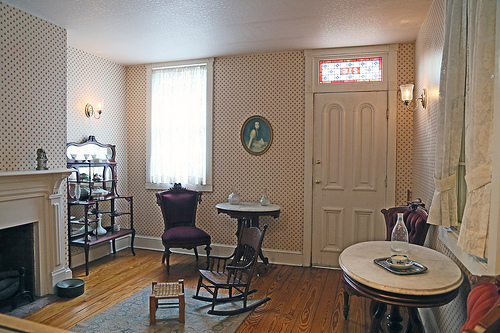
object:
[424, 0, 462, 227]
curtain tie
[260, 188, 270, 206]
lamp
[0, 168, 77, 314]
fire place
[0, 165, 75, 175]
mantle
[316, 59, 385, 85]
window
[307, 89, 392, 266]
door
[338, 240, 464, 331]
table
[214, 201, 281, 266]
table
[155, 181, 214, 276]
chair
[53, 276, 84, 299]
black object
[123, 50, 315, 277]
wal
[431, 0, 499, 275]
curtain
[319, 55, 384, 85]
glass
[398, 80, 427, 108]
light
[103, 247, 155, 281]
floor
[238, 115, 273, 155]
picture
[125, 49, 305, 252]
wall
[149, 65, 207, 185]
curtain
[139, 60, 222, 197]
window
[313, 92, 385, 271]
white door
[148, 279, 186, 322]
stand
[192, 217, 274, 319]
chair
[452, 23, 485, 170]
window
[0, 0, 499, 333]
room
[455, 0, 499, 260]
tie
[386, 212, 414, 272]
glass bottle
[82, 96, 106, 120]
lamp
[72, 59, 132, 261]
wall